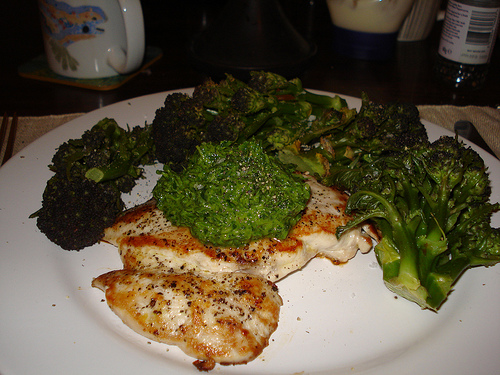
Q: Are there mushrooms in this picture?
A: No, there are no mushrooms.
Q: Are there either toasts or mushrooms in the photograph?
A: No, there are no mushrooms or toasts.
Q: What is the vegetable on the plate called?
A: The vegetable is broccoli.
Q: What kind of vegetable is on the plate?
A: The vegetable is broccoli.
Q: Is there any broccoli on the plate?
A: Yes, there is broccoli on the plate.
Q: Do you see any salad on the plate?
A: No, there is broccoli on the plate.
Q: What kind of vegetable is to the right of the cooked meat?
A: The vegetable is broccoli.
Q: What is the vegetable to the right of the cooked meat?
A: The vegetable is broccoli.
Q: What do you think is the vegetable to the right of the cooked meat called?
A: The vegetable is broccoli.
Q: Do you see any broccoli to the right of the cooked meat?
A: Yes, there is broccoli to the right of the meat.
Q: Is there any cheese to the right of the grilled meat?
A: No, there is broccoli to the right of the meat.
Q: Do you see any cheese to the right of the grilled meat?
A: No, there is broccoli to the right of the meat.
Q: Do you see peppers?
A: Yes, there is a pepper.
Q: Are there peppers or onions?
A: Yes, there is a pepper.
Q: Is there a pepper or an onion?
A: Yes, there is a pepper.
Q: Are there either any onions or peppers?
A: Yes, there is a pepper.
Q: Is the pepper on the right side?
A: Yes, the pepper is on the right of the image.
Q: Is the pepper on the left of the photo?
A: No, the pepper is on the right of the image.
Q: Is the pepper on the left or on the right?
A: The pepper is on the right of the image.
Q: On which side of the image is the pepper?
A: The pepper is on the right of the image.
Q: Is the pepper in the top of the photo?
A: Yes, the pepper is in the top of the image.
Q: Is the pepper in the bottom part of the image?
A: No, the pepper is in the top of the image.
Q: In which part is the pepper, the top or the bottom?
A: The pepper is in the top of the image.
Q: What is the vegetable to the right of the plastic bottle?
A: The vegetable is a pepper.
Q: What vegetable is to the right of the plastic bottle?
A: The vegetable is a pepper.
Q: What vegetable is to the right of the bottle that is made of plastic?
A: The vegetable is a pepper.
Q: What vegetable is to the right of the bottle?
A: The vegetable is a pepper.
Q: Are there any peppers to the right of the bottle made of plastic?
A: Yes, there is a pepper to the right of the bottle.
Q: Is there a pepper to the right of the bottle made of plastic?
A: Yes, there is a pepper to the right of the bottle.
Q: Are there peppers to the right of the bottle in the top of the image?
A: Yes, there is a pepper to the right of the bottle.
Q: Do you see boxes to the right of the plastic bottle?
A: No, there is a pepper to the right of the bottle.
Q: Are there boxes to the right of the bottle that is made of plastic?
A: No, there is a pepper to the right of the bottle.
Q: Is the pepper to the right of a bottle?
A: Yes, the pepper is to the right of a bottle.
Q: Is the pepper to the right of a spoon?
A: No, the pepper is to the right of a bottle.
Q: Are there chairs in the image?
A: No, there are no chairs.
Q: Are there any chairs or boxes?
A: No, there are no chairs or boxes.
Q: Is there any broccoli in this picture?
A: Yes, there is broccoli.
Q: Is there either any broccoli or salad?
A: Yes, there is broccoli.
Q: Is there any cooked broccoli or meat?
A: Yes, there is cooked broccoli.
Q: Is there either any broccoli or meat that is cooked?
A: Yes, the broccoli is cooked.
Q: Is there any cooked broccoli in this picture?
A: Yes, there is cooked broccoli.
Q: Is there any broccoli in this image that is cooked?
A: Yes, there is broccoli that is cooked.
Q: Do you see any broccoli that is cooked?
A: Yes, there is broccoli that is cooked.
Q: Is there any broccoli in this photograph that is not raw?
A: Yes, there is cooked broccoli.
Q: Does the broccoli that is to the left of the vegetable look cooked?
A: Yes, the broccoli is cooked.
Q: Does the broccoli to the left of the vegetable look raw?
A: No, the broccoli is cooked.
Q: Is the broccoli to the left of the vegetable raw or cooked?
A: The broccoli is cooked.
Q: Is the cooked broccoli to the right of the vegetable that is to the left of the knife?
A: No, the broccoli is to the left of the vegetable.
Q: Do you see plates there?
A: Yes, there is a plate.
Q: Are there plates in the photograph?
A: Yes, there is a plate.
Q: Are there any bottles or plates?
A: Yes, there is a plate.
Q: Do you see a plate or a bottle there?
A: Yes, there is a plate.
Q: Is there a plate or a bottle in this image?
A: Yes, there is a plate.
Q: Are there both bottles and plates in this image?
A: Yes, there are both a plate and a bottle.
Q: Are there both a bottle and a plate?
A: Yes, there are both a plate and a bottle.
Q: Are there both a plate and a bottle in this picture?
A: Yes, there are both a plate and a bottle.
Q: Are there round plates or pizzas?
A: Yes, there is a round plate.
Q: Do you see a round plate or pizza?
A: Yes, there is a round plate.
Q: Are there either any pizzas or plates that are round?
A: Yes, the plate is round.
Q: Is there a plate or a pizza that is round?
A: Yes, the plate is round.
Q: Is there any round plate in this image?
A: Yes, there is a round plate.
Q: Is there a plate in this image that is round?
A: Yes, there is a plate that is round.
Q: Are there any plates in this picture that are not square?
A: Yes, there is a round plate.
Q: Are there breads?
A: No, there are no breads.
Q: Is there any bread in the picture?
A: No, there is no breads.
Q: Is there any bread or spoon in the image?
A: No, there are no breads or spoons.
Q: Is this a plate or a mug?
A: This is a plate.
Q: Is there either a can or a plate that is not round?
A: No, there is a plate but it is round.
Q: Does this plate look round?
A: Yes, the plate is round.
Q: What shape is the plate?
A: The plate is round.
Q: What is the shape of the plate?
A: The plate is round.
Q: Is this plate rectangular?
A: No, the plate is round.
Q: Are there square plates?
A: No, there is a plate but it is round.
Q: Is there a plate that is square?
A: No, there is a plate but it is round.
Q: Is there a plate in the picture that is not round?
A: No, there is a plate but it is round.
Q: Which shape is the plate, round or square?
A: The plate is round.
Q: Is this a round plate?
A: Yes, this is a round plate.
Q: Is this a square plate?
A: No, this is a round plate.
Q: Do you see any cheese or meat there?
A: Yes, there is meat.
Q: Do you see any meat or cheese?
A: Yes, there is meat.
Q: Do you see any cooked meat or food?
A: Yes, there is cooked meat.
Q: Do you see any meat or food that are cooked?
A: Yes, the meat is cooked.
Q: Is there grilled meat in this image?
A: Yes, there is grilled meat.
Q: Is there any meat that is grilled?
A: Yes, there is meat that is grilled.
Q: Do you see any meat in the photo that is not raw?
A: Yes, there is grilled meat.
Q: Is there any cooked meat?
A: Yes, there is cooked meat.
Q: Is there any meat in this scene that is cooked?
A: Yes, there is meat that is cooked.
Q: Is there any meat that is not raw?
A: Yes, there is cooked meat.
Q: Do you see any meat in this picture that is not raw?
A: Yes, there is cooked meat.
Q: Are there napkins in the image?
A: No, there are no napkins.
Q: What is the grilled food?
A: The food is meat.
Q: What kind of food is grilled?
A: The food is meat.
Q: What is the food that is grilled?
A: The food is meat.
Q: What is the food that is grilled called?
A: The food is meat.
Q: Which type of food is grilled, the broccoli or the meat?
A: The meat is grilled.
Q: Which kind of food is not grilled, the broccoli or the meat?
A: The broccoli is not grilled.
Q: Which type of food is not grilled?
A: The food is broccoli.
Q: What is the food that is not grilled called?
A: The food is broccoli.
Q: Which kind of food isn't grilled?
A: The food is broccoli.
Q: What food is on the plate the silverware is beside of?
A: The food is meat.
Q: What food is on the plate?
A: The food is meat.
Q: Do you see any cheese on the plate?
A: No, there is meat on the plate.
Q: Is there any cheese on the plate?
A: No, there is meat on the plate.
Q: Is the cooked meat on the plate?
A: Yes, the meat is on the plate.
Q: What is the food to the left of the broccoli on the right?
A: The food is meat.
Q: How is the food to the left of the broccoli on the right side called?
A: The food is meat.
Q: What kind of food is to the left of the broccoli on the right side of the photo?
A: The food is meat.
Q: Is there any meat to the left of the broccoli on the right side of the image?
A: Yes, there is meat to the left of the broccoli.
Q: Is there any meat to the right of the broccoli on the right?
A: No, the meat is to the left of the broccoli.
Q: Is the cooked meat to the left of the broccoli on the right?
A: Yes, the meat is to the left of the broccoli.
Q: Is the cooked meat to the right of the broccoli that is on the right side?
A: No, the meat is to the left of the broccoli.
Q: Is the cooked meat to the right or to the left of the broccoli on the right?
A: The meat is to the left of the broccoli.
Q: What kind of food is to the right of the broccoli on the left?
A: The food is meat.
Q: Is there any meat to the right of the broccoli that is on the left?
A: Yes, there is meat to the right of the broccoli.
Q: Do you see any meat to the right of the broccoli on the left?
A: Yes, there is meat to the right of the broccoli.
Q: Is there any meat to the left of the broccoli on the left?
A: No, the meat is to the right of the broccoli.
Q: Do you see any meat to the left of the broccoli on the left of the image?
A: No, the meat is to the right of the broccoli.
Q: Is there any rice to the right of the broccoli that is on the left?
A: No, there is meat to the right of the broccoli.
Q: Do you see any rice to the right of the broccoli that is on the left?
A: No, there is meat to the right of the broccoli.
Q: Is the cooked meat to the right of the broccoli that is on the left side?
A: Yes, the meat is to the right of the broccoli.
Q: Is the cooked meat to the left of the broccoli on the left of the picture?
A: No, the meat is to the right of the broccoli.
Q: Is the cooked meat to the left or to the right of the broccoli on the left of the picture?
A: The meat is to the right of the broccoli.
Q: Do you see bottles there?
A: Yes, there is a bottle.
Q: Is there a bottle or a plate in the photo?
A: Yes, there is a bottle.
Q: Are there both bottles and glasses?
A: No, there is a bottle but no glasses.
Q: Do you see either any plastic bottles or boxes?
A: Yes, there is a plastic bottle.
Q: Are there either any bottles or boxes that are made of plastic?
A: Yes, the bottle is made of plastic.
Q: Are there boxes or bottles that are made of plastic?
A: Yes, the bottle is made of plastic.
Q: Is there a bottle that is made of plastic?
A: Yes, there is a bottle that is made of plastic.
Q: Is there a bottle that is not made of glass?
A: Yes, there is a bottle that is made of plastic.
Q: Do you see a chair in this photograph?
A: No, there are no chairs.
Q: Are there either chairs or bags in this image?
A: No, there are no chairs or bags.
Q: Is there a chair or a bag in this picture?
A: No, there are no chairs or bags.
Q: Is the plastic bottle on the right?
A: Yes, the bottle is on the right of the image.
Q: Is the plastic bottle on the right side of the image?
A: Yes, the bottle is on the right of the image.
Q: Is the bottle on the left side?
A: No, the bottle is on the right of the image.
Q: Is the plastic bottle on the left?
A: No, the bottle is on the right of the image.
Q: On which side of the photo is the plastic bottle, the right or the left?
A: The bottle is on the right of the image.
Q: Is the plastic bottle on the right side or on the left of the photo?
A: The bottle is on the right of the image.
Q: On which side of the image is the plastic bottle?
A: The bottle is on the right of the image.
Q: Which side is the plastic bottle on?
A: The bottle is on the right of the image.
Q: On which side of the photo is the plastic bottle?
A: The bottle is on the right of the image.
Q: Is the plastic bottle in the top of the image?
A: Yes, the bottle is in the top of the image.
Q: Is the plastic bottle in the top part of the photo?
A: Yes, the bottle is in the top of the image.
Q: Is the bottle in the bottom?
A: No, the bottle is in the top of the image.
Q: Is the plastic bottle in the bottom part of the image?
A: No, the bottle is in the top of the image.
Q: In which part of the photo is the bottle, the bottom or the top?
A: The bottle is in the top of the image.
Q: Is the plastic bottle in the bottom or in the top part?
A: The bottle is in the top of the image.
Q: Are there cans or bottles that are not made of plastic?
A: No, there is a bottle but it is made of plastic.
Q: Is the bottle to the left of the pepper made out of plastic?
A: Yes, the bottle is made of plastic.